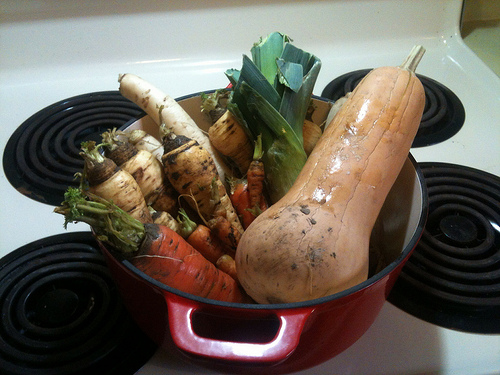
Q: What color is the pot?
A: Red.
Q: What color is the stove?
A: White.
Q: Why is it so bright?
A: Lights on.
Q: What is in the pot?
A: Veggies.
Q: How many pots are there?
A: One.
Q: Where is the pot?
A: The stove.